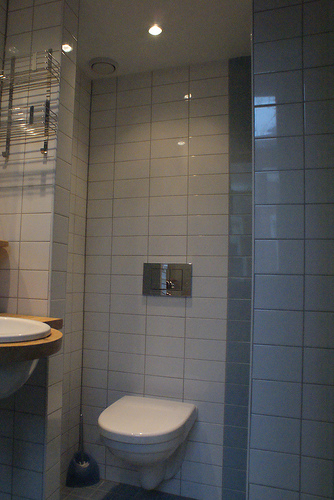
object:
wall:
[60, 64, 94, 499]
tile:
[253, 69, 303, 107]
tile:
[302, 98, 333, 136]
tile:
[254, 136, 304, 171]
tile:
[255, 170, 305, 205]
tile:
[253, 204, 305, 240]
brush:
[66, 414, 101, 489]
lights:
[61, 44, 73, 54]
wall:
[41, 1, 79, 497]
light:
[148, 24, 163, 37]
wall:
[80, 53, 250, 500]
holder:
[66, 450, 100, 489]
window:
[142, 262, 193, 298]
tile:
[150, 157, 189, 178]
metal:
[40, 96, 50, 154]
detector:
[90, 57, 117, 75]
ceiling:
[76, 0, 253, 83]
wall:
[245, 0, 334, 500]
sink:
[0, 314, 52, 400]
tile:
[185, 317, 226, 341]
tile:
[110, 292, 147, 315]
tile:
[109, 332, 146, 354]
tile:
[146, 315, 185, 338]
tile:
[146, 335, 185, 358]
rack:
[0, 48, 61, 158]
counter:
[0, 311, 64, 355]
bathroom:
[0, 0, 334, 500]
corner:
[76, 73, 95, 478]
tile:
[227, 299, 252, 321]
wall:
[0, 0, 65, 318]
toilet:
[96, 395, 198, 492]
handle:
[77, 413, 84, 453]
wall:
[0, 355, 48, 499]